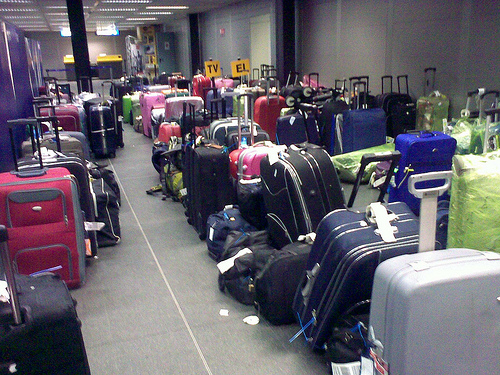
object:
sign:
[230, 59, 251, 79]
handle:
[274, 148, 291, 160]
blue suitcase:
[388, 131, 457, 219]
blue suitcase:
[330, 107, 387, 156]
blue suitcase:
[291, 201, 441, 353]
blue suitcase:
[88, 105, 118, 159]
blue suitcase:
[275, 113, 306, 147]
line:
[106, 160, 215, 375]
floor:
[58, 121, 394, 375]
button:
[32, 205, 43, 211]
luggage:
[0, 117, 86, 289]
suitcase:
[259, 144, 346, 253]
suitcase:
[253, 76, 288, 143]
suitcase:
[366, 170, 499, 375]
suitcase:
[0, 224, 92, 375]